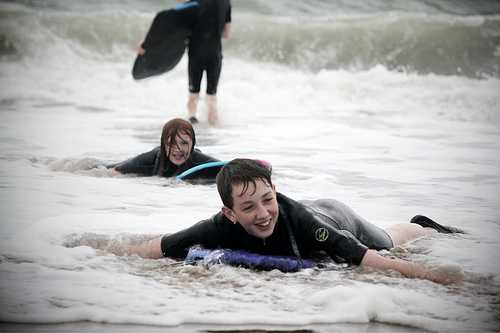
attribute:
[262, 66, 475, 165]
water — foamy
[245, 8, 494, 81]
waves — grey, crashing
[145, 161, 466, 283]
boy — smiling, laying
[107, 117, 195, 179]
girl — body boarding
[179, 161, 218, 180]
surfboard — light blue, black, blue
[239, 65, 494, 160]
foam — white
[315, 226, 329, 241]
emblem — white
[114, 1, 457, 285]
kids — floating, laying, swimming